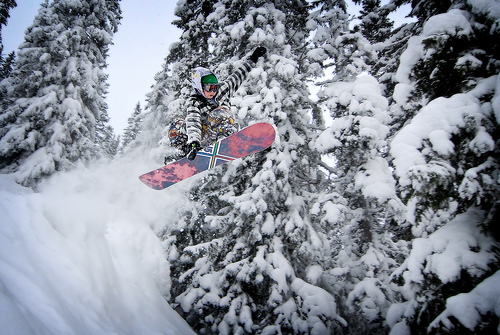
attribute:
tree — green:
[152, 0, 499, 331]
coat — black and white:
[174, 63, 256, 149]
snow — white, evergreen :
[2, 0, 498, 331]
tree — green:
[168, 50, 398, 331]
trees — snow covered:
[0, 2, 497, 333]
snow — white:
[0, 0, 114, 170]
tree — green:
[0, 1, 124, 183]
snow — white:
[252, 245, 294, 292]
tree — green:
[172, 10, 399, 332]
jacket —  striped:
[182, 56, 256, 145]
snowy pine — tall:
[7, 5, 119, 199]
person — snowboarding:
[189, 60, 221, 104]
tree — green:
[5, 5, 112, 162]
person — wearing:
[159, 36, 273, 173]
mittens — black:
[239, 40, 282, 66]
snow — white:
[49, 290, 144, 325]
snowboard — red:
[129, 121, 294, 194]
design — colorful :
[190, 139, 231, 173]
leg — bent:
[168, 110, 183, 152]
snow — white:
[0, 0, 122, 185]